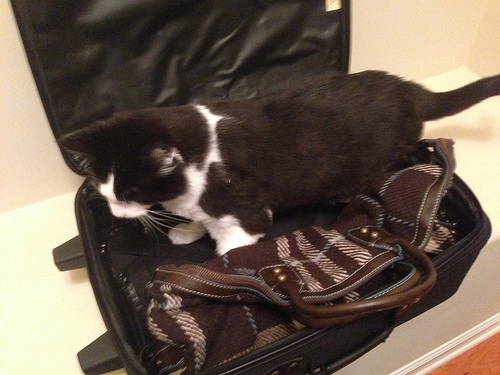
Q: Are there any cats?
A: Yes, there is a cat.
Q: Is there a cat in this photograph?
A: Yes, there is a cat.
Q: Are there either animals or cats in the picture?
A: Yes, there is a cat.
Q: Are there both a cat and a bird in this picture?
A: No, there is a cat but no birds.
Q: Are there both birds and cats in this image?
A: No, there is a cat but no birds.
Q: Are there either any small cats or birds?
A: Yes, there is a small cat.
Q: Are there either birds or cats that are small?
A: Yes, the cat is small.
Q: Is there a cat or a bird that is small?
A: Yes, the cat is small.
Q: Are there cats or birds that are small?
A: Yes, the cat is small.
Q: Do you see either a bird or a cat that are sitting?
A: Yes, the cat is sitting.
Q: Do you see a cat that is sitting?
A: Yes, there is a cat that is sitting.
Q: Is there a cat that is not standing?
A: Yes, there is a cat that is sitting.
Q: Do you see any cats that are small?
A: Yes, there is a small cat.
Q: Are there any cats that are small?
A: Yes, there is a cat that is small.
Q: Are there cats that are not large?
A: Yes, there is a small cat.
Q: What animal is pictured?
A: The animal is a cat.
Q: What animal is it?
A: The animal is a cat.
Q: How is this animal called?
A: This is a cat.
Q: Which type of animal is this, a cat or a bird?
A: This is a cat.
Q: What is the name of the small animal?
A: The animal is a cat.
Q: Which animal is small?
A: The animal is a cat.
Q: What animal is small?
A: The animal is a cat.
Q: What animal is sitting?
A: The animal is a cat.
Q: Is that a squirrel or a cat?
A: That is a cat.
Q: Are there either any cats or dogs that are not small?
A: No, there is a cat but it is small.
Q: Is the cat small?
A: Yes, the cat is small.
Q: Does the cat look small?
A: Yes, the cat is small.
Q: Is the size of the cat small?
A: Yes, the cat is small.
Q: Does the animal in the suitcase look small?
A: Yes, the cat is small.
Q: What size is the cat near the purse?
A: The cat is small.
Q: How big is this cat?
A: The cat is small.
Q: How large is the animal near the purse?
A: The cat is small.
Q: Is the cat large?
A: No, the cat is small.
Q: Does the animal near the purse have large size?
A: No, the cat is small.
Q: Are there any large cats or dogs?
A: No, there is a cat but it is small.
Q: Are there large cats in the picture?
A: No, there is a cat but it is small.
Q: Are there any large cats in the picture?
A: No, there is a cat but it is small.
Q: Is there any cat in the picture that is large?
A: No, there is a cat but it is small.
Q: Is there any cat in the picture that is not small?
A: No, there is a cat but it is small.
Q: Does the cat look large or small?
A: The cat is small.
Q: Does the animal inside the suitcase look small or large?
A: The cat is small.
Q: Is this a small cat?
A: Yes, this is a small cat.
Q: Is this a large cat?
A: No, this is a small cat.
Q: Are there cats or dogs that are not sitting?
A: No, there is a cat but it is sitting.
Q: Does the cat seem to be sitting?
A: Yes, the cat is sitting.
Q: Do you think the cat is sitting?
A: Yes, the cat is sitting.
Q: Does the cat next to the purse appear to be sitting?
A: Yes, the cat is sitting.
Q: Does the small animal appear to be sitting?
A: Yes, the cat is sitting.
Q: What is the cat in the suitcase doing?
A: The cat is sitting.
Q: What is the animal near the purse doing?
A: The cat is sitting.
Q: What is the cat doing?
A: The cat is sitting.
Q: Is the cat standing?
A: No, the cat is sitting.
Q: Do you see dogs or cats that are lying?
A: No, there is a cat but it is sitting.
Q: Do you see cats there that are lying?
A: No, there is a cat but it is sitting.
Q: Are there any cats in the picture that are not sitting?
A: No, there is a cat but it is sitting.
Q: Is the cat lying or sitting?
A: The cat is sitting.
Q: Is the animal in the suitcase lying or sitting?
A: The cat is sitting.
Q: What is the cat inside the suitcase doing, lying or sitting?
A: The cat is sitting.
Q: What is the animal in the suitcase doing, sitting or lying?
A: The cat is sitting.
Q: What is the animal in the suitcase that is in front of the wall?
A: The animal is a cat.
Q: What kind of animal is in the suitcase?
A: The animal is a cat.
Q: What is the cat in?
A: The cat is in the suitcase.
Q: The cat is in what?
A: The cat is in the suitcase.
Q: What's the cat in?
A: The cat is in the suitcase.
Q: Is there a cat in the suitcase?
A: Yes, there is a cat in the suitcase.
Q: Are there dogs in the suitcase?
A: No, there is a cat in the suitcase.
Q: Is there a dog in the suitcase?
A: No, there is a cat in the suitcase.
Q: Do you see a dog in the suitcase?
A: No, there is a cat in the suitcase.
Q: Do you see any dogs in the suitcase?
A: No, there is a cat in the suitcase.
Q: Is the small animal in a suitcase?
A: Yes, the cat is in a suitcase.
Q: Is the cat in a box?
A: No, the cat is in a suitcase.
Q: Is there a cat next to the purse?
A: Yes, there is a cat next to the purse.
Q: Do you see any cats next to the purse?
A: Yes, there is a cat next to the purse.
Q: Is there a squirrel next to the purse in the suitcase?
A: No, there is a cat next to the purse.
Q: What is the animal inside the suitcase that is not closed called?
A: The animal is a cat.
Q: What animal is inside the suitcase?
A: The animal is a cat.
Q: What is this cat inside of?
A: The cat is inside the suitcase.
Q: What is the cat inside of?
A: The cat is inside the suitcase.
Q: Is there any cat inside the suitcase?
A: Yes, there is a cat inside the suitcase.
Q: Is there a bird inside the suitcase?
A: No, there is a cat inside the suitcase.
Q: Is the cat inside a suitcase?
A: Yes, the cat is inside a suitcase.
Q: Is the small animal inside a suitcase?
A: Yes, the cat is inside a suitcase.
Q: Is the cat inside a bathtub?
A: No, the cat is inside a suitcase.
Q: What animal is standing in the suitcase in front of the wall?
A: The cat is standing in the suitcase.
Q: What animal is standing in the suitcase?
A: The cat is standing in the suitcase.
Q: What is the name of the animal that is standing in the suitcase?
A: The animal is a cat.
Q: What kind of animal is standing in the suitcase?
A: The animal is a cat.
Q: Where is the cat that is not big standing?
A: The cat is standing in the suitcase.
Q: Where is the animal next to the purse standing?
A: The cat is standing in the suitcase.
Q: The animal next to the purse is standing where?
A: The cat is standing in the suitcase.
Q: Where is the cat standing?
A: The cat is standing in the suitcase.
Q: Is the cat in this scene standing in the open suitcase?
A: Yes, the cat is standing in the suitcase.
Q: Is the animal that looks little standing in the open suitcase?
A: Yes, the cat is standing in the suitcase.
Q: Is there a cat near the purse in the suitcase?
A: Yes, there is a cat near the purse.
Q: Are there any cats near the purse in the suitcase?
A: Yes, there is a cat near the purse.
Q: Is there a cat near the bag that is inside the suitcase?
A: Yes, there is a cat near the purse.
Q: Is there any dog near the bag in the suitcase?
A: No, there is a cat near the purse.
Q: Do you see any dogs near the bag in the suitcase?
A: No, there is a cat near the purse.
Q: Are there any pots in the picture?
A: No, there are no pots.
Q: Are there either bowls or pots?
A: No, there are no pots or bowls.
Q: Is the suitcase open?
A: Yes, the suitcase is open.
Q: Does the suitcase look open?
A: Yes, the suitcase is open.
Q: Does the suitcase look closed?
A: No, the suitcase is open.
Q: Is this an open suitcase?
A: Yes, this is an open suitcase.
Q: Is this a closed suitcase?
A: No, this is an open suitcase.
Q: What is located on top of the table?
A: The suitcase is on top of the table.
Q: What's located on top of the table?
A: The suitcase is on top of the table.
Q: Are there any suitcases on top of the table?
A: Yes, there is a suitcase on top of the table.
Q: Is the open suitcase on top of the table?
A: Yes, the suitcase is on top of the table.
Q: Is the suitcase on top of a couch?
A: No, the suitcase is on top of the table.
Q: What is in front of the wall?
A: The suitcase is in front of the wall.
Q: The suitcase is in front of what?
A: The suitcase is in front of the wall.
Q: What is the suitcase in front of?
A: The suitcase is in front of the wall.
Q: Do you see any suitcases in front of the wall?
A: Yes, there is a suitcase in front of the wall.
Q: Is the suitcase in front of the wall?
A: Yes, the suitcase is in front of the wall.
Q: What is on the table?
A: The suitcase is on the table.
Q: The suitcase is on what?
A: The suitcase is on the table.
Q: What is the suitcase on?
A: The suitcase is on the table.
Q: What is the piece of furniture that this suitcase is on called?
A: The piece of furniture is a table.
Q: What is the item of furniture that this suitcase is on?
A: The piece of furniture is a table.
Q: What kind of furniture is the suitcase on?
A: The suitcase is on the table.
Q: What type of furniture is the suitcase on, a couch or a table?
A: The suitcase is on a table.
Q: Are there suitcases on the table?
A: Yes, there is a suitcase on the table.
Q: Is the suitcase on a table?
A: Yes, the suitcase is on a table.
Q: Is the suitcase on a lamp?
A: No, the suitcase is on a table.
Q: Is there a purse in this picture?
A: Yes, there is a purse.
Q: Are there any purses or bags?
A: Yes, there is a purse.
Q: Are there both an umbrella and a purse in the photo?
A: No, there is a purse but no umbrellas.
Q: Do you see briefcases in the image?
A: No, there are no briefcases.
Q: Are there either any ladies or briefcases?
A: No, there are no briefcases or ladies.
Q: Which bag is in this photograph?
A: The bag is a purse.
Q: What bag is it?
A: The bag is a purse.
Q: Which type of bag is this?
A: This is a purse.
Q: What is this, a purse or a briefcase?
A: This is a purse.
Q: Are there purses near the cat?
A: Yes, there is a purse near the cat.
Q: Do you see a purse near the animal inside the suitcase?
A: Yes, there is a purse near the cat.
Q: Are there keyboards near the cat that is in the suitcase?
A: No, there is a purse near the cat.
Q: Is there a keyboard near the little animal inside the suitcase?
A: No, there is a purse near the cat.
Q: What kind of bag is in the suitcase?
A: The bag is a purse.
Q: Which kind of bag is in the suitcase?
A: The bag is a purse.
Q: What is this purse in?
A: The purse is in the suitcase.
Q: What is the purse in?
A: The purse is in the suitcase.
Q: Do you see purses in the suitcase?
A: Yes, there is a purse in the suitcase.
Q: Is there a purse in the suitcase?
A: Yes, there is a purse in the suitcase.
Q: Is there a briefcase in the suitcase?
A: No, there is a purse in the suitcase.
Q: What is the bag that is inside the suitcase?
A: The bag is a purse.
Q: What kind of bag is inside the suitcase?
A: The bag is a purse.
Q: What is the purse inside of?
A: The purse is inside the suitcase.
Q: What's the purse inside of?
A: The purse is inside the suitcase.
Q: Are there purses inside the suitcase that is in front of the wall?
A: Yes, there is a purse inside the suitcase.